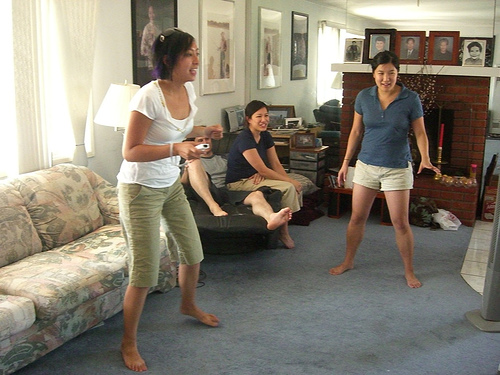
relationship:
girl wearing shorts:
[325, 51, 442, 289] [352, 156, 414, 193]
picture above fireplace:
[344, 35, 364, 64] [330, 58, 494, 228]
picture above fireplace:
[362, 27, 395, 60] [330, 58, 494, 228]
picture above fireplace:
[396, 28, 426, 62] [330, 58, 494, 228]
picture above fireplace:
[426, 28, 460, 64] [330, 58, 494, 228]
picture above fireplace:
[462, 34, 487, 66] [330, 58, 494, 228]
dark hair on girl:
[150, 27, 196, 81] [110, 15, 245, 321]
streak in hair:
[149, 46, 160, 78] [144, 15, 199, 81]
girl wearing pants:
[119, 29, 223, 372] [114, 177, 204, 289]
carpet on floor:
[10, 200, 499, 373] [7, 171, 499, 373]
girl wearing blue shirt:
[328, 51, 443, 291] [351, 82, 424, 169]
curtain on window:
[38, 20, 115, 140] [18, 8, 108, 170]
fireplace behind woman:
[340, 73, 479, 225] [329, 50, 443, 289]